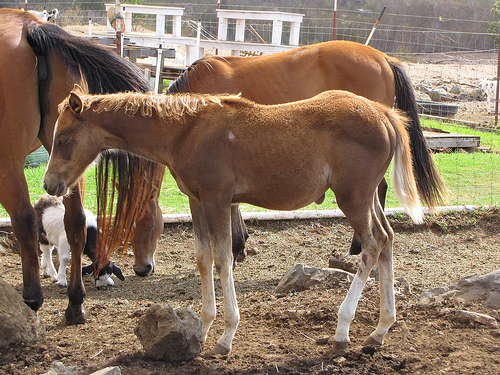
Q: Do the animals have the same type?
A: No, there are both horses and goats.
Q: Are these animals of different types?
A: Yes, they are horses and goats.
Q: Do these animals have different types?
A: Yes, they are horses and goats.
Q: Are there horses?
A: Yes, there is a horse.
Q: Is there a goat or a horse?
A: Yes, there is a horse.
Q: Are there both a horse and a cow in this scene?
A: No, there is a horse but no cows.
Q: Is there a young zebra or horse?
A: Yes, there is a young horse.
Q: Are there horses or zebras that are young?
A: Yes, the horse is young.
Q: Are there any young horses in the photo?
A: Yes, there is a young horse.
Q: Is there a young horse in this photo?
A: Yes, there is a young horse.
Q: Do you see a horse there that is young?
A: Yes, there is a horse that is young.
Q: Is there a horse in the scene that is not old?
A: Yes, there is an young horse.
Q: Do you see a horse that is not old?
A: Yes, there is an young horse.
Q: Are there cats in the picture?
A: No, there are no cats.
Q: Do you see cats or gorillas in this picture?
A: No, there are no cats or gorillas.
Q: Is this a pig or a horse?
A: This is a horse.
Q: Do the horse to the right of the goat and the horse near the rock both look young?
A: Yes, both the horse and the horse are young.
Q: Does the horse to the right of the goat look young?
A: Yes, the horse is young.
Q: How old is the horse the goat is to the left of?
A: The horse is young.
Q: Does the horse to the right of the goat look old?
A: No, the horse is young.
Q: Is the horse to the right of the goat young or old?
A: The horse is young.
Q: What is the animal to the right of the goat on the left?
A: The animal is a horse.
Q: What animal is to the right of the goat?
A: The animal is a horse.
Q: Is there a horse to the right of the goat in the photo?
A: Yes, there is a horse to the right of the goat.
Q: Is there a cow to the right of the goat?
A: No, there is a horse to the right of the goat.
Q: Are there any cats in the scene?
A: No, there are no cats.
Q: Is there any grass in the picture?
A: Yes, there is grass.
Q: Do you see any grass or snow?
A: Yes, there is grass.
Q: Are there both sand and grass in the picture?
A: No, there is grass but no sand.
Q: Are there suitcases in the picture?
A: No, there are no suitcases.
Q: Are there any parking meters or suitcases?
A: No, there are no suitcases or parking meters.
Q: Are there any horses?
A: Yes, there is a horse.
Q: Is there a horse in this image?
A: Yes, there is a horse.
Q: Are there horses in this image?
A: Yes, there is a horse.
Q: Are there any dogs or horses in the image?
A: Yes, there is a horse.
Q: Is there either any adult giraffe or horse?
A: Yes, there is an adult horse.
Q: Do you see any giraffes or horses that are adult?
A: Yes, the horse is adult.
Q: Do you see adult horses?
A: Yes, there is an adult horse.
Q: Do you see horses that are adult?
A: Yes, there is a horse that is adult.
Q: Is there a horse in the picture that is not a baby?
A: Yes, there is a adult horse.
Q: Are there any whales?
A: No, there are no whales.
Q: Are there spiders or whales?
A: No, there are no whales or spiders.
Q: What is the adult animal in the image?
A: The animal is a horse.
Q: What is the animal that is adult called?
A: The animal is a horse.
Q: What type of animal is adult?
A: The animal is a horse.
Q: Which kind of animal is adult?
A: The animal is a horse.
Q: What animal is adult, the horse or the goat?
A: The horse is adult.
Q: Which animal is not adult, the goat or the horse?
A: The goat is not adult.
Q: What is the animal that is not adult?
A: The animal is a goat.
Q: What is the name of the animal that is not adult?
A: The animal is a goat.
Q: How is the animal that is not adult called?
A: The animal is a goat.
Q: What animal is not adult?
A: The animal is a goat.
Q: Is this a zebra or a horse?
A: This is a horse.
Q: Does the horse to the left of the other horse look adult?
A: Yes, the horse is adult.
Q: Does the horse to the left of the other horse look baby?
A: No, the horse is adult.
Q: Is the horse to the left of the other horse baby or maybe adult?
A: The horse is adult.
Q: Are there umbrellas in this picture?
A: No, there are no umbrellas.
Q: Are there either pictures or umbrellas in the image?
A: No, there are no umbrellas or pictures.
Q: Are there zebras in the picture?
A: No, there are no zebras.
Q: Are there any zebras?
A: No, there are no zebras.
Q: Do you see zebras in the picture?
A: No, there are no zebras.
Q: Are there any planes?
A: No, there are no planes.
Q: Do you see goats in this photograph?
A: Yes, there is a goat.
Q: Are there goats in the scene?
A: Yes, there is a goat.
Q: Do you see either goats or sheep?
A: Yes, there is a goat.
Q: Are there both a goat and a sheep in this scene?
A: No, there is a goat but no sheep.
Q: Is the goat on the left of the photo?
A: Yes, the goat is on the left of the image.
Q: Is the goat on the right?
A: No, the goat is on the left of the image.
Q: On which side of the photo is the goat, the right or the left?
A: The goat is on the left of the image.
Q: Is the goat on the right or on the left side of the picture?
A: The goat is on the left of the image.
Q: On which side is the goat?
A: The goat is on the left of the image.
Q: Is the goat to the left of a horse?
A: Yes, the goat is to the left of a horse.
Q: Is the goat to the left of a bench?
A: No, the goat is to the left of a horse.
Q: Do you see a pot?
A: No, there are no pots.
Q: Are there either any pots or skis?
A: No, there are no pots or skis.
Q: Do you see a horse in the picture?
A: Yes, there is a horse.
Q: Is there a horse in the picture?
A: Yes, there is a horse.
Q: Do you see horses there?
A: Yes, there is a horse.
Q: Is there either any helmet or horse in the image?
A: Yes, there is a horse.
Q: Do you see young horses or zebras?
A: Yes, there is a young horse.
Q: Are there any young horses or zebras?
A: Yes, there is a young horse.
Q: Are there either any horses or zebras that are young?
A: Yes, the horse is young.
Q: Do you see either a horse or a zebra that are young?
A: Yes, the horse is young.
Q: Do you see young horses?
A: Yes, there is a young horse.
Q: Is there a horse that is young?
A: Yes, there is a horse that is young.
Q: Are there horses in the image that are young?
A: Yes, there is a horse that is young.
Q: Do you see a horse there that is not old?
A: Yes, there is an young horse.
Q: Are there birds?
A: No, there are no birds.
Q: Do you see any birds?
A: No, there are no birds.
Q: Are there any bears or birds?
A: No, there are no birds or bears.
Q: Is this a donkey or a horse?
A: This is a horse.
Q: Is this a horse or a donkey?
A: This is a horse.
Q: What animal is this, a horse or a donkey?
A: This is a horse.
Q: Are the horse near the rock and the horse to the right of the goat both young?
A: Yes, both the horse and the horse are young.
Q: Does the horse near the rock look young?
A: Yes, the horse is young.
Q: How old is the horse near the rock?
A: The horse is young.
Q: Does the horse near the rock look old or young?
A: The horse is young.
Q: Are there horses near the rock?
A: Yes, there is a horse near the rock.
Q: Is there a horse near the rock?
A: Yes, there is a horse near the rock.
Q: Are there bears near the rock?
A: No, there is a horse near the rock.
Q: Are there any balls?
A: No, there are no balls.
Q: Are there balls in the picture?
A: No, there are no balls.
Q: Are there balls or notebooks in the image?
A: No, there are no balls or notebooks.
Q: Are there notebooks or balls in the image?
A: No, there are no balls or notebooks.